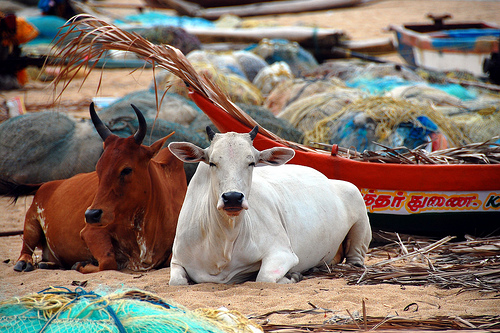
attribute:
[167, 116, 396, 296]
cow — looking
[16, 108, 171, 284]
bull — brown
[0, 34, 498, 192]
net — fishing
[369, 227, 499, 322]
sticks — piled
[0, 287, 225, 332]
buoys — blue circle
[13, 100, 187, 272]
cow — brown , white 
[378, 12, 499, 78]
row boat — small 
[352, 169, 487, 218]
lettering — red 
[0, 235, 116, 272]
hooves — black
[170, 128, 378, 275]
cow — white 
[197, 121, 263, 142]
horns — black 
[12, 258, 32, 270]
hoof — black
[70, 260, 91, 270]
hoof — black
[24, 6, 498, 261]
boat — pointy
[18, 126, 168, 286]
cow — brown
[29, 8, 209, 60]
fabric — grey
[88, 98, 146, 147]
horns — dark, curved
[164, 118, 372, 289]
cow — white